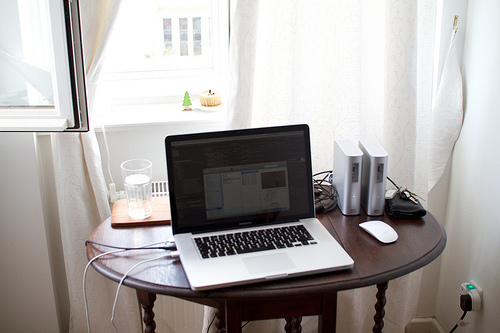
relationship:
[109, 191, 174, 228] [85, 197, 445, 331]
tray on table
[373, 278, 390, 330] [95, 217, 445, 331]
leg of table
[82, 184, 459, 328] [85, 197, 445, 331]
wooden leg of table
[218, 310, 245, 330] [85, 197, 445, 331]
wooden leg of table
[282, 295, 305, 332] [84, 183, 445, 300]
leg of table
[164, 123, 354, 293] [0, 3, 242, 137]
computer near window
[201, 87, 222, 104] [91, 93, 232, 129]
decoration on window sill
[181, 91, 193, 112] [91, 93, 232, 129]
christmas tree on window sill